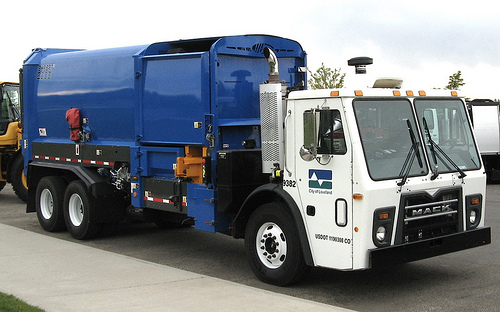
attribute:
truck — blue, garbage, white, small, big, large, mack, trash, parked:
[25, 49, 304, 238]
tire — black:
[245, 180, 303, 274]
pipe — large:
[257, 30, 301, 211]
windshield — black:
[338, 85, 486, 146]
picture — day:
[3, 24, 440, 288]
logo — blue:
[301, 174, 340, 203]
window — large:
[353, 88, 465, 181]